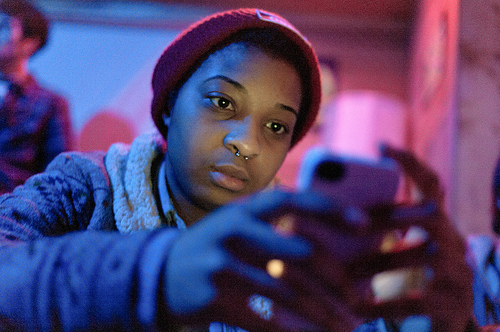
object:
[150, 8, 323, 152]
hat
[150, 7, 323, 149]
fabric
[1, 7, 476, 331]
girl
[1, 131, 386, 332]
sweater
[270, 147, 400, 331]
phone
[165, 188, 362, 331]
hand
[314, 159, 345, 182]
lens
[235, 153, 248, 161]
ring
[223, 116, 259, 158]
nose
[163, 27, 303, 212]
head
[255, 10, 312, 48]
label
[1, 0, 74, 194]
man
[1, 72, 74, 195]
shirt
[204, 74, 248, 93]
eyebrow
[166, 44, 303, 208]
face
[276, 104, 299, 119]
eyebrow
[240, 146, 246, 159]
septum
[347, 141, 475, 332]
hand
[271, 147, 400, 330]
phone case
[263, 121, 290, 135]
eye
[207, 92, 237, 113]
eye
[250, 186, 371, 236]
finger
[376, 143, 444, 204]
finger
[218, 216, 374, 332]
finger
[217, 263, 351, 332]
finger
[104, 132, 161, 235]
scarf